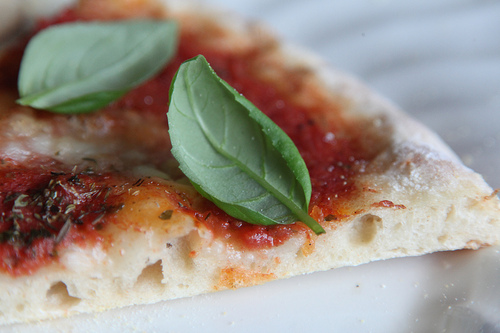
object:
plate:
[1, 0, 500, 332]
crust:
[1, 0, 498, 325]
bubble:
[137, 259, 165, 290]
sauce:
[0, 0, 367, 279]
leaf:
[166, 53, 324, 236]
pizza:
[0, 0, 500, 316]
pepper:
[307, 118, 315, 129]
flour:
[384, 142, 444, 197]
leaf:
[17, 19, 181, 115]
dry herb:
[0, 153, 128, 276]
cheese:
[2, 103, 189, 199]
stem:
[183, 64, 323, 235]